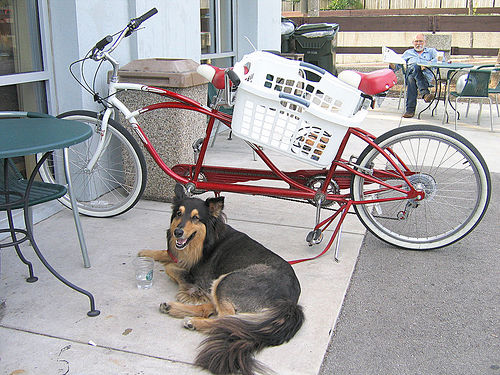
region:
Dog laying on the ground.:
[136, 188, 310, 373]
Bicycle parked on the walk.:
[36, 25, 498, 251]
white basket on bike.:
[222, 35, 372, 176]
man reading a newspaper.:
[380, 32, 441, 114]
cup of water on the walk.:
[130, 253, 161, 288]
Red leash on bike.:
[277, 194, 362, 271]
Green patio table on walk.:
[0, 98, 103, 319]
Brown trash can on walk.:
[110, 48, 215, 208]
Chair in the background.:
[444, 65, 499, 132]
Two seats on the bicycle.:
[30, 23, 489, 255]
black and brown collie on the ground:
[141, 184, 302, 373]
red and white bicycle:
[39, 8, 491, 250]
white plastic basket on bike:
[227, 49, 367, 151]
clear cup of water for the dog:
[133, 256, 155, 286]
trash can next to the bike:
[111, 58, 213, 198]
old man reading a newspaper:
[382, 30, 441, 118]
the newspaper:
[382, 46, 419, 66]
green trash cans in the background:
[282, 19, 336, 74]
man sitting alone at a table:
[387, 35, 498, 124]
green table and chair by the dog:
[2, 112, 100, 317]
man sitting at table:
[400, 34, 467, 117]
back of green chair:
[445, 68, 491, 129]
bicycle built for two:
[38, 8, 492, 250]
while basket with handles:
[231, 48, 372, 168]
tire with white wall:
[353, 123, 492, 251]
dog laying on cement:
[135, 182, 302, 372]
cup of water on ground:
[131, 254, 154, 287]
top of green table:
[0, 116, 90, 158]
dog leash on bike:
[283, 200, 353, 265]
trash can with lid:
[111, 58, 211, 202]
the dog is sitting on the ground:
[160, 183, 333, 372]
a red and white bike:
[89, 120, 497, 220]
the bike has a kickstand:
[312, 166, 359, 276]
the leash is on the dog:
[177, 195, 454, 332]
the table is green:
[29, 99, 114, 296]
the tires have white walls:
[348, 120, 497, 258]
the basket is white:
[222, 100, 475, 240]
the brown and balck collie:
[133, 226, 243, 318]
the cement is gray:
[374, 267, 459, 343]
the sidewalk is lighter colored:
[42, 305, 127, 367]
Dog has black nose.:
[168, 224, 181, 232]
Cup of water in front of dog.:
[127, 249, 172, 317]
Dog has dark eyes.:
[171, 203, 216, 227]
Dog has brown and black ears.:
[171, 183, 245, 228]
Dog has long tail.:
[212, 311, 261, 361]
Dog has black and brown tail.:
[225, 300, 275, 369]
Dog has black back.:
[228, 236, 252, 256]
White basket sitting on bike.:
[218, 67, 329, 134]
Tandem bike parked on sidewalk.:
[109, 52, 400, 258]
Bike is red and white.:
[95, 75, 397, 235]